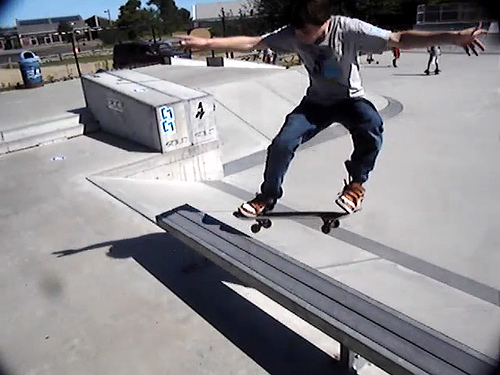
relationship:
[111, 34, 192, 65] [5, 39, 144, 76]
suv in parking lot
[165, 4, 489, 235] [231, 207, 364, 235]
boy on skate board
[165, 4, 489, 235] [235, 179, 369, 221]
boy with shoes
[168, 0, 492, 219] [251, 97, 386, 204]
boy with jeans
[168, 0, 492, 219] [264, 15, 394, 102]
boy with shirt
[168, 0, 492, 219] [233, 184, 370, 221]
boy with shoes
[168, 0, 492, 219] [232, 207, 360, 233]
boy on skateboard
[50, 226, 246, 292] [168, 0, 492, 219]
shadow of boy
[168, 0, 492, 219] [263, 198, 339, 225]
boy jumping with h skateboard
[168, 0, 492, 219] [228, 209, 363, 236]
boy jumping with skateboard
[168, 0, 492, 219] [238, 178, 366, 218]
boy wearing a pair of sneakers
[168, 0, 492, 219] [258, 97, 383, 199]
boy wear jeans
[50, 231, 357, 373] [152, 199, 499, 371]
shadow reflected from ramp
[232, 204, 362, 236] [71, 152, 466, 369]
skate board on ramp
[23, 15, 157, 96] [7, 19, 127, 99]
building on street